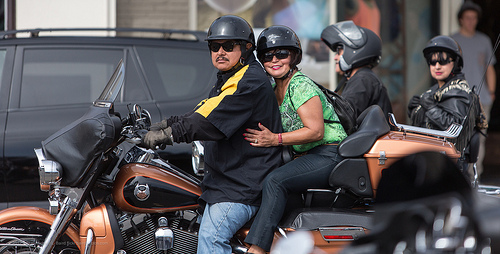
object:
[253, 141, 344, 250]
jeans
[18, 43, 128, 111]
window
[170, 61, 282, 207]
shirt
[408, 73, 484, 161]
jacket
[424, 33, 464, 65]
helmet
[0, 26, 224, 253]
car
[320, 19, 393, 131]
man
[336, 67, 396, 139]
jacket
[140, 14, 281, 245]
man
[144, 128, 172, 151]
gloves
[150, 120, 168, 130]
gloves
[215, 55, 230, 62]
mustache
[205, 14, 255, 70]
head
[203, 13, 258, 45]
helmet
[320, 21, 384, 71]
helmet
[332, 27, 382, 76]
head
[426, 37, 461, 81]
head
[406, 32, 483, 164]
person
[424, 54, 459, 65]
sunglasses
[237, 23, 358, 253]
passenger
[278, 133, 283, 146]
bracelet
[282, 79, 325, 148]
arm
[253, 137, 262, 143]
ring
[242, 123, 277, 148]
hand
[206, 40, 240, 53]
sunglasses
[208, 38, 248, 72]
face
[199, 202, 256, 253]
jeans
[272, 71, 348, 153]
blouse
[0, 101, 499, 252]
bike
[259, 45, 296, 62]
sunglasses